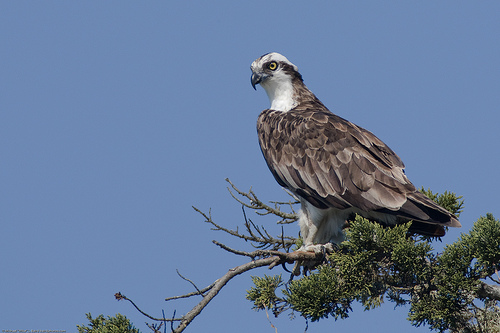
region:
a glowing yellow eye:
[267, 59, 279, 72]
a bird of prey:
[246, 45, 462, 257]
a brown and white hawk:
[243, 50, 461, 264]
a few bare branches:
[161, 268, 212, 301]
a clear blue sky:
[5, 32, 182, 224]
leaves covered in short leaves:
[281, 212, 403, 318]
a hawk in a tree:
[243, 45, 458, 280]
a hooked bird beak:
[248, 70, 263, 92]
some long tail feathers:
[381, 190, 459, 239]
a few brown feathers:
[273, 114, 350, 172]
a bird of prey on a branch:
[228, 21, 447, 266]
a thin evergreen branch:
[115, 221, 472, 331]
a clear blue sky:
[12, 11, 490, 331]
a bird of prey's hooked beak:
[242, 68, 268, 98]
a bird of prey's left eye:
[263, 58, 280, 73]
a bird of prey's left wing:
[260, 130, 420, 210]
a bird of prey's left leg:
[287, 203, 338, 259]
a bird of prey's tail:
[409, 203, 464, 244]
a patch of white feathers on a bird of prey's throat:
[261, 82, 288, 112]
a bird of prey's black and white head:
[235, 50, 337, 103]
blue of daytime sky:
[4, 2, 496, 329]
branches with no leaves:
[131, 180, 299, 323]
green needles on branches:
[259, 214, 496, 331]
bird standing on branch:
[249, 49, 453, 257]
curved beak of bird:
[249, 70, 260, 90]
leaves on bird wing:
[258, 111, 411, 211]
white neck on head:
[249, 52, 306, 113]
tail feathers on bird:
[399, 196, 461, 237]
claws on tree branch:
[291, 244, 342, 266]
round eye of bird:
[269, 60, 278, 71]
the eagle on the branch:
[246, 39, 456, 265]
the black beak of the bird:
[244, 67, 264, 94]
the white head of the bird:
[246, 50, 302, 107]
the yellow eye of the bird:
[269, 60, 278, 71]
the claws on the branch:
[286, 243, 339, 261]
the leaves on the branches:
[241, 209, 440, 332]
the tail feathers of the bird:
[389, 176, 464, 239]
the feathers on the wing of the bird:
[254, 108, 401, 204]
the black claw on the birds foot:
[317, 239, 328, 252]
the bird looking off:
[236, 41, 461, 263]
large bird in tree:
[242, 25, 388, 235]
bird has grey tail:
[408, 172, 445, 225]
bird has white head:
[240, 39, 299, 100]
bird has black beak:
[242, 46, 279, 104]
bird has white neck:
[242, 58, 289, 128]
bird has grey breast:
[257, 108, 351, 230]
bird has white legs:
[297, 89, 333, 268]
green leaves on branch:
[274, 225, 446, 325]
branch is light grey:
[133, 209, 290, 331]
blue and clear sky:
[17, 90, 224, 246]